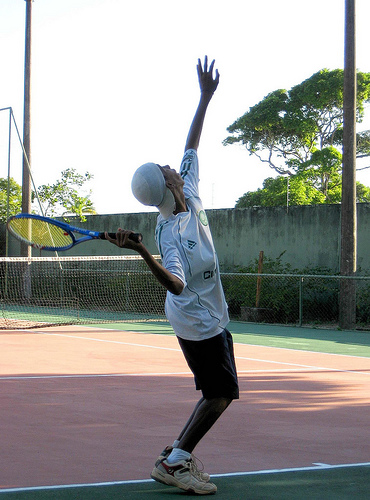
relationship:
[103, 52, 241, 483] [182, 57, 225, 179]
man has arm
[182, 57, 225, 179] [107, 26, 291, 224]
arm in air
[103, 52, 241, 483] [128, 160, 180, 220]
man wearing hat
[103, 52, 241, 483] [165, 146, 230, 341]
man wearing shirt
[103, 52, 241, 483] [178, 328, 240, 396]
man wearing shorts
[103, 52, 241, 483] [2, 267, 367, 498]
man on tennis court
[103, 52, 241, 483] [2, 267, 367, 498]
man in tennis court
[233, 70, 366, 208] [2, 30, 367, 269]
tree in background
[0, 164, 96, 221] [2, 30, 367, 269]
tree in background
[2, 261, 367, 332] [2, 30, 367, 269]
fence in background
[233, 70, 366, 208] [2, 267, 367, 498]
tree next to tennis court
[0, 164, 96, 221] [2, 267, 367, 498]
tree next to tennis court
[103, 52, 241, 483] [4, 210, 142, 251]
man holding tennis racket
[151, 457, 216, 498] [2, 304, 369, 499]
sneakers are on floor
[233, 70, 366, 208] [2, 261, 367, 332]
tree behind fence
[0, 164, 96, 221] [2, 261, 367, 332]
tree behind fence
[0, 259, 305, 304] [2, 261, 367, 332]
bushes are beside fence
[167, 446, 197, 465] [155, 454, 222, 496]
sock on feet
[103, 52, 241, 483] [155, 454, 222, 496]
man has feet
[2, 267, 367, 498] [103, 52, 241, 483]
tennis court behind man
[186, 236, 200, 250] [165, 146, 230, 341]
logo in shirt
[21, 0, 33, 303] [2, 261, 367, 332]
pole behind fence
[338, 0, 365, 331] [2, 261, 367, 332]
pole behind fence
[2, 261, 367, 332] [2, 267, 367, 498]
fence around tennis court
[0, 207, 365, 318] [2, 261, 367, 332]
wall behind fence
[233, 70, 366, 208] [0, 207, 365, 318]
tree behind wall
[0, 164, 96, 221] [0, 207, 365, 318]
tree behind wall